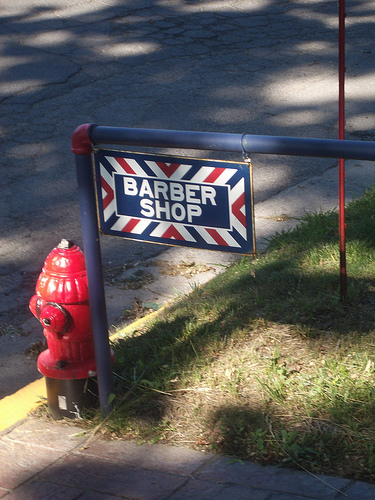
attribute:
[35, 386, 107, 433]
base — black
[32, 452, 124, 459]
brick — gray and concrete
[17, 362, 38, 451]
line — yellow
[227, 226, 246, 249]
line — blue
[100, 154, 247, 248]
background — white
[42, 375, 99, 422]
bottom — black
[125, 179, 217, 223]
words — BARBER SHOP,  white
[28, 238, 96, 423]
fire hydrant — RED, BLACK,  red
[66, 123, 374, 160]
pole — navy blue, red, blue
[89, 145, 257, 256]
sign — barber shop sign, hanging, red, white and blue, blue, white, red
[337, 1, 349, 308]
pole —  red, dark red, red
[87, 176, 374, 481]
grass — partially brown